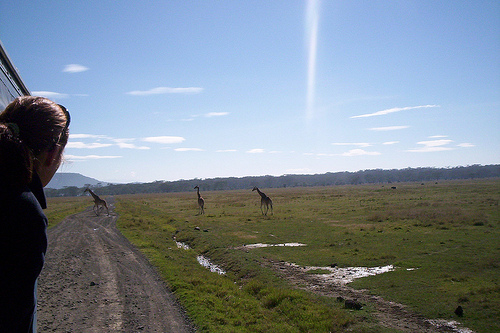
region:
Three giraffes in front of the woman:
[72, 177, 281, 219]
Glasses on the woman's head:
[32, 101, 74, 145]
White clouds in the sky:
[74, 128, 196, 164]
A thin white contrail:
[288, 2, 329, 120]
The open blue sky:
[99, 9, 256, 59]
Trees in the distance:
[107, 173, 489, 190]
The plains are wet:
[245, 232, 379, 289]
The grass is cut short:
[348, 230, 464, 302]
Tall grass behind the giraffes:
[271, 189, 311, 204]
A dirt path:
[60, 215, 115, 312]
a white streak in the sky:
[293, 1, 334, 106]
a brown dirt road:
[44, 218, 175, 329]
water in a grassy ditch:
[165, 226, 229, 304]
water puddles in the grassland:
[231, 232, 402, 310]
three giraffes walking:
[68, 172, 301, 222]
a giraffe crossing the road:
[76, 176, 125, 215]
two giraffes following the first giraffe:
[171, 166, 281, 226]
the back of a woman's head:
[4, 86, 90, 173]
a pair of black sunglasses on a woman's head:
[35, 89, 94, 164]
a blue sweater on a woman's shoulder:
[6, 179, 58, 271]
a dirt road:
[35, 199, 188, 331]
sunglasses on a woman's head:
[58, 103, 70, 136]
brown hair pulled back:
[0, 93, 67, 184]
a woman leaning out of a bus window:
[1, 84, 74, 331]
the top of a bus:
[0, 41, 41, 116]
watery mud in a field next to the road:
[310, 258, 399, 286]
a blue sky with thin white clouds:
[0, 1, 498, 177]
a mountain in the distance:
[42, 168, 109, 194]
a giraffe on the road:
[81, 183, 118, 222]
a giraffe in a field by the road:
[249, 179, 280, 218]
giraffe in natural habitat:
[243, 182, 279, 219]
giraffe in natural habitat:
[185, 168, 212, 225]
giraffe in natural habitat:
[80, 180, 111, 222]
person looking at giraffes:
[5, 85, 95, 312]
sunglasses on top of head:
[41, 93, 80, 132]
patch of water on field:
[328, 254, 390, 293]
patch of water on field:
[251, 233, 300, 258]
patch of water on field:
[191, 244, 225, 282]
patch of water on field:
[400, 303, 462, 330]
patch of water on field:
[167, 228, 194, 250]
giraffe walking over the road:
[79, 181, 116, 224]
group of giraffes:
[77, 181, 293, 228]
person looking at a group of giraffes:
[0, 88, 84, 331]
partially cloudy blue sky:
[2, 3, 495, 166]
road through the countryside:
[20, 191, 201, 328]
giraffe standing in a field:
[240, 180, 282, 217]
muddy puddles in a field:
[166, 226, 420, 291]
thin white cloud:
[110, 73, 214, 105]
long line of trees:
[55, 158, 496, 200]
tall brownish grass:
[356, 193, 491, 237]